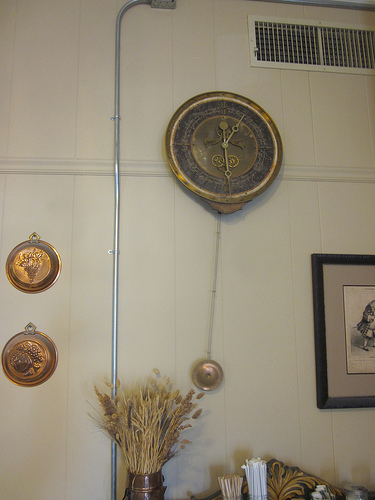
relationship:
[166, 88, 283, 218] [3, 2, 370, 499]
clock on wall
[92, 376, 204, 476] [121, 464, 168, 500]
wheat in vase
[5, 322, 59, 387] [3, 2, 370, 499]
bronze on wall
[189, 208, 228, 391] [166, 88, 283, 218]
pendulum on clock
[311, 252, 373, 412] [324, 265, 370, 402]
border of picture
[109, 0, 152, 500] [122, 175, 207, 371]
pipe on wall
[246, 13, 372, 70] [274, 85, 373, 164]
vent in wall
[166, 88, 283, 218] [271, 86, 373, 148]
clock on wall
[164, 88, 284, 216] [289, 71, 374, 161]
clock on wall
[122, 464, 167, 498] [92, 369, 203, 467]
vase has plants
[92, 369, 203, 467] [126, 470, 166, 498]
plants in vase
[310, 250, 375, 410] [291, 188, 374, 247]
art on wall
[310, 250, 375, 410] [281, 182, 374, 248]
art on wall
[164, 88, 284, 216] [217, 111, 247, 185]
clock has arms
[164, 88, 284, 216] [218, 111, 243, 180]
clock has arms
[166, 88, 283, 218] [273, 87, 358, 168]
clock on wall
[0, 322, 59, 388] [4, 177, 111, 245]
bronze on wall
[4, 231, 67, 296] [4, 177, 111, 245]
pot on wall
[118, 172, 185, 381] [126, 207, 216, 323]
paneling on wall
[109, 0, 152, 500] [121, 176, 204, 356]
pipe on wall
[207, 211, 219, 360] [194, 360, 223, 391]
stick on bell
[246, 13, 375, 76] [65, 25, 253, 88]
vent in wall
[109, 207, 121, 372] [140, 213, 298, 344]
pipe attached to wall